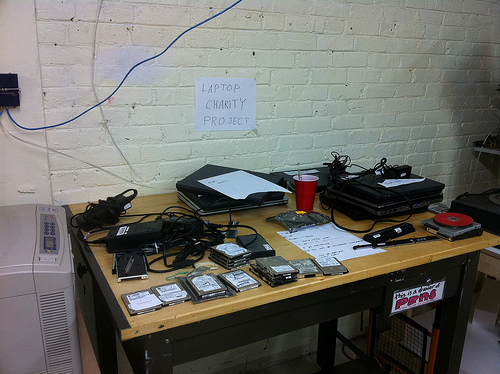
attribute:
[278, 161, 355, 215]
cup — red, plastic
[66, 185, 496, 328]
table top — wooden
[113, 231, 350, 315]
drives — solid, state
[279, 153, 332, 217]
cup — red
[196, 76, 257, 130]
sign — handwritten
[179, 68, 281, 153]
text — black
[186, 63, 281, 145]
sign — white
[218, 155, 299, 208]
cd — red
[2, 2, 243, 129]
cord — blue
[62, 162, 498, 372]
desk — wood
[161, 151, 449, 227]
computers — laptop